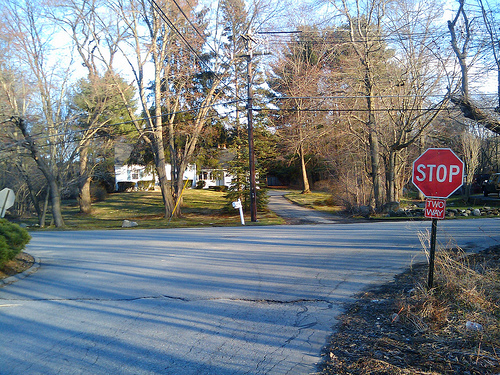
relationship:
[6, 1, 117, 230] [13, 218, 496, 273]
tree growing across street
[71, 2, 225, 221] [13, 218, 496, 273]
tree growing across street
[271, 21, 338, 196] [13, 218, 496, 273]
tree growing across street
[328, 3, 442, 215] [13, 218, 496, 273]
tree growing across street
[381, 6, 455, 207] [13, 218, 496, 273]
tree growing across street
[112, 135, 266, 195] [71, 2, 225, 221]
house behind tree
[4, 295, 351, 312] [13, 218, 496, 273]
crack in street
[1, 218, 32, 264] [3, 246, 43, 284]
bush growing on corner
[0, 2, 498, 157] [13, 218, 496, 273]
electric lines above street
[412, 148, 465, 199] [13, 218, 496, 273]
sign on side of street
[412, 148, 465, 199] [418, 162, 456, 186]
sign says stop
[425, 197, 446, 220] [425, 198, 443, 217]
sign says two way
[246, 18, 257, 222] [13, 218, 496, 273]
pole on side of street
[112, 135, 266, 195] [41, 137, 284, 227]
house in wooded area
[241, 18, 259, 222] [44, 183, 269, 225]
pole in yard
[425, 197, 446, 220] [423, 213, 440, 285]
sign on pole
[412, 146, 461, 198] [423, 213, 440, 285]
sign on pole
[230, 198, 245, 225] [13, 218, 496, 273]
mailbox beside street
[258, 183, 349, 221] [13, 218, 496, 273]
driveway off street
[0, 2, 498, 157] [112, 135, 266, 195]
electric lines in front of house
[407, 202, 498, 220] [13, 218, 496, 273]
rock wall along street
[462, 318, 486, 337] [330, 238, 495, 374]
trash on ground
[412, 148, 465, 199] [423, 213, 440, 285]
sign on pole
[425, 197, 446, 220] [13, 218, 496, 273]
sign on side of street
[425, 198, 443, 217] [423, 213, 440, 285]
two way on pole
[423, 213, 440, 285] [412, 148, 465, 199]
pole with a sign